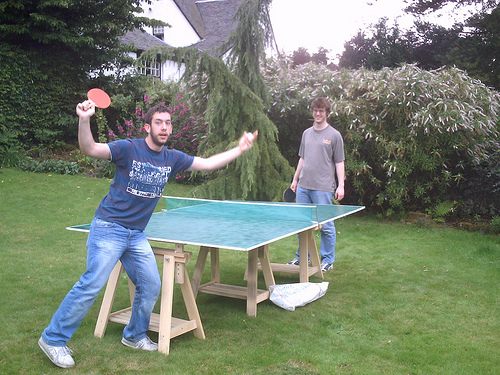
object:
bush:
[105, 88, 208, 180]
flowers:
[182, 109, 189, 118]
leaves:
[6, 5, 26, 21]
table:
[66, 191, 366, 357]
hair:
[309, 97, 330, 117]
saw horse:
[93, 240, 217, 358]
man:
[290, 93, 355, 280]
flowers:
[142, 92, 154, 101]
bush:
[0, 1, 499, 235]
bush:
[108, 56, 500, 232]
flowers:
[458, 120, 473, 132]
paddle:
[82, 86, 111, 112]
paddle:
[281, 186, 298, 203]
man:
[35, 97, 260, 369]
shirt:
[92, 134, 192, 233]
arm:
[75, 115, 127, 161]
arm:
[174, 144, 241, 172]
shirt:
[295, 121, 345, 191]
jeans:
[291, 183, 337, 263]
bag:
[267, 278, 330, 312]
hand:
[236, 129, 258, 153]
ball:
[244, 130, 254, 140]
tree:
[1, 1, 500, 233]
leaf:
[46, 107, 50, 114]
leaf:
[29, 78, 35, 83]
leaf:
[5, 87, 10, 91]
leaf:
[26, 60, 31, 64]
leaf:
[56, 66, 58, 69]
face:
[147, 109, 171, 147]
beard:
[148, 128, 170, 145]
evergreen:
[130, 1, 297, 202]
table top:
[64, 200, 366, 254]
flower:
[383, 91, 393, 99]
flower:
[426, 111, 434, 121]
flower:
[416, 77, 428, 87]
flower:
[336, 81, 345, 90]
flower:
[390, 165, 398, 175]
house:
[86, 1, 282, 86]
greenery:
[1, 0, 173, 174]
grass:
[1, 168, 498, 373]